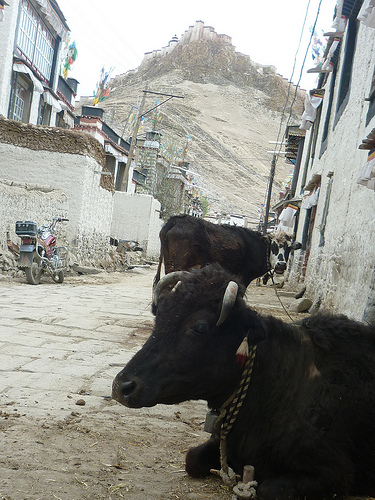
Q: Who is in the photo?
A: Nobody.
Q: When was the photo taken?
A: During the day.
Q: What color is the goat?
A: Black.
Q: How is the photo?
A: Clear.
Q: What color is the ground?
A: Grey.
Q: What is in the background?
A: Buildings.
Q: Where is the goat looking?
A: Sideways.